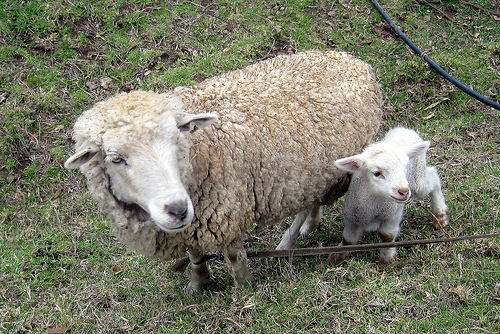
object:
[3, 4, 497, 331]
field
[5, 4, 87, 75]
weeds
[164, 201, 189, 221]
nose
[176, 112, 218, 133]
ear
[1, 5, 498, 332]
grass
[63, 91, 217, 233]
head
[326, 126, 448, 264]
baby lamb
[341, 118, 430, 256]
sheep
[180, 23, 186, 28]
brown grass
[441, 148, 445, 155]
brown grass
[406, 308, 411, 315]
brown grass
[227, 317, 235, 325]
brown grass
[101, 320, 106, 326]
brown grass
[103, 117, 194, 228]
face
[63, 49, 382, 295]
bearded man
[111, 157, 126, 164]
eye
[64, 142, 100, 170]
ear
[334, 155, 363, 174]
ear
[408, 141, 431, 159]
ear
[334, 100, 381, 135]
wool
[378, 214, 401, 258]
leg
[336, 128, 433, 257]
body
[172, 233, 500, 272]
rope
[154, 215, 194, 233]
mouth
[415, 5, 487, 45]
brown leaves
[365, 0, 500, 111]
cable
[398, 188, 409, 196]
nose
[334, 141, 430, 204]
head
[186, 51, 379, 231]
body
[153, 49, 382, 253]
coat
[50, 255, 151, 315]
patch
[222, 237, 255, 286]
leg